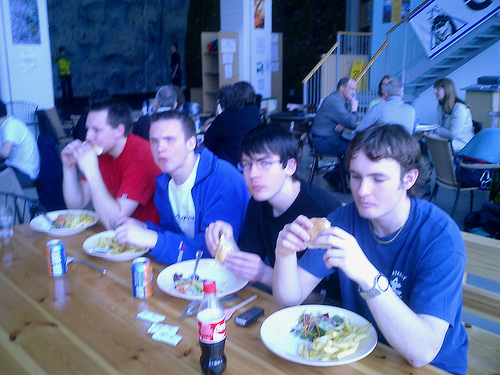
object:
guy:
[61, 100, 163, 231]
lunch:
[29, 205, 102, 234]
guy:
[113, 109, 253, 267]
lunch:
[96, 232, 147, 255]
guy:
[203, 121, 343, 304]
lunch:
[172, 272, 222, 297]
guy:
[270, 122, 470, 374]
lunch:
[290, 308, 373, 362]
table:
[1, 210, 448, 373]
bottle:
[196, 279, 227, 375]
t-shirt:
[81, 132, 163, 225]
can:
[45, 239, 68, 278]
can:
[131, 257, 154, 300]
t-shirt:
[166, 153, 206, 240]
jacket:
[144, 147, 251, 265]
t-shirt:
[236, 178, 344, 302]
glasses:
[237, 157, 289, 171]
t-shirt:
[296, 195, 469, 375]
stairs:
[301, 0, 500, 132]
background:
[0, 0, 499, 137]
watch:
[358, 273, 389, 300]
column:
[219, 0, 284, 120]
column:
[1, 1, 56, 110]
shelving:
[200, 31, 239, 117]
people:
[311, 75, 474, 194]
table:
[341, 124, 446, 142]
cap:
[203, 279, 217, 294]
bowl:
[29, 209, 99, 239]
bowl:
[82, 229, 157, 262]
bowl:
[156, 258, 250, 301]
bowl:
[259, 303, 379, 367]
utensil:
[188, 250, 203, 281]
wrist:
[355, 271, 382, 288]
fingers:
[311, 226, 353, 249]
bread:
[301, 217, 331, 249]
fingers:
[281, 214, 314, 252]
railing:
[301, 31, 372, 122]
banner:
[407, 0, 499, 62]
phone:
[234, 306, 264, 327]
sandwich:
[82, 140, 104, 156]